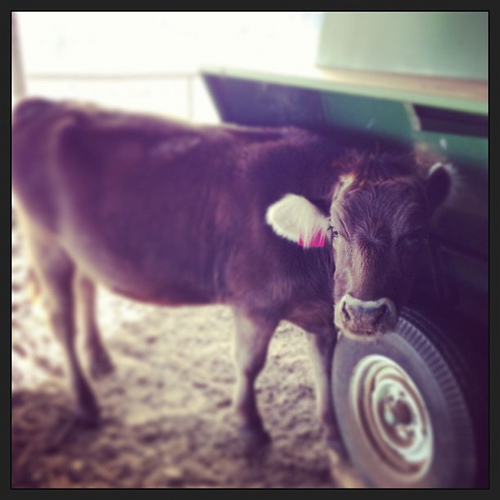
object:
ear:
[261, 191, 333, 254]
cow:
[12, 93, 460, 489]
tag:
[297, 230, 326, 251]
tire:
[329, 314, 490, 488]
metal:
[347, 352, 435, 484]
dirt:
[8, 227, 338, 489]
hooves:
[64, 392, 104, 426]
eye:
[329, 229, 340, 240]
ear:
[424, 158, 457, 211]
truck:
[195, 11, 490, 495]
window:
[12, 12, 321, 121]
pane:
[12, 22, 25, 103]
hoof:
[233, 419, 273, 452]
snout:
[330, 293, 399, 341]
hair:
[332, 151, 413, 226]